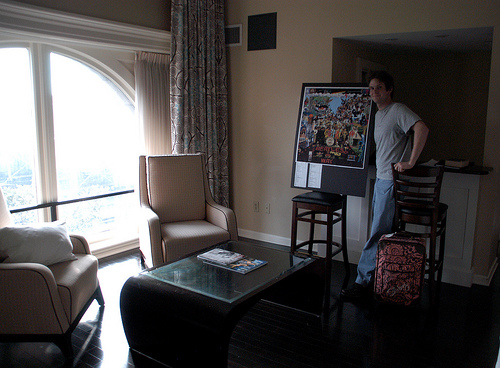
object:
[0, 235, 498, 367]
floor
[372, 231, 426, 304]
luggage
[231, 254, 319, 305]
edge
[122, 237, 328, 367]
table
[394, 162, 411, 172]
hand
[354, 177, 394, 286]
trouser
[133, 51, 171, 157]
curtain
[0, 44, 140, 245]
window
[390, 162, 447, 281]
stool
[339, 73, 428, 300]
man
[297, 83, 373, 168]
photograph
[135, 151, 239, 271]
chair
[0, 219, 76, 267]
pillow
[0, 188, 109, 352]
chair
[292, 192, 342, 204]
seat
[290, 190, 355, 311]
stool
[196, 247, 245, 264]
magazine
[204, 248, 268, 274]
magazine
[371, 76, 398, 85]
hair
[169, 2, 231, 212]
drapes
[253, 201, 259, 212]
socket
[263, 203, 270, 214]
socket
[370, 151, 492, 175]
counter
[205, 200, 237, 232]
arm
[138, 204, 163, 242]
arm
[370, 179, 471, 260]
molding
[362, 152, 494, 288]
bar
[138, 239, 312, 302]
top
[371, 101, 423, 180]
part